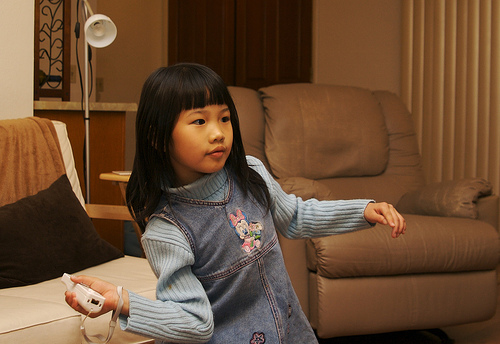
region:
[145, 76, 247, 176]
the head of a girl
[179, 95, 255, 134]
the eyes of a girl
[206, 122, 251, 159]
the nose of a girl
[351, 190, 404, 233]
the hand of a girl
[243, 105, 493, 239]
the arm of a girl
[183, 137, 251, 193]
the lips of a girl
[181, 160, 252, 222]
the chin of a girl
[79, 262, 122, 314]
the thumb of a girl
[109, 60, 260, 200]
the hair of a girl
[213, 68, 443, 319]
a couch in a house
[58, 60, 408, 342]
a little girl playing a video game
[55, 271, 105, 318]
a Wii remote in the girl's right hand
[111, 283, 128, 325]
a wrist strap on the girl's right wrist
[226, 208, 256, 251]
Minnie Mouse on the girl's denim dress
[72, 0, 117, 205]
a lamp in the family room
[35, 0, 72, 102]
a decorative wrought iron piece on the counter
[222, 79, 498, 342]
a beige leather recliner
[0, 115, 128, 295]
a blanket draped over the back of the sofa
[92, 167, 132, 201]
a wooden table behind the girl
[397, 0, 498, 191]
long blinds on the window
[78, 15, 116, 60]
lamp in the corner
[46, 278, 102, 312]
wii remote in hand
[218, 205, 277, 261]
minnie mouse on jumper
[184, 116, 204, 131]
eye of little girl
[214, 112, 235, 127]
eye of little girl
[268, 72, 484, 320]
recliner in the corner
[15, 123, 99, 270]
blanket in the corner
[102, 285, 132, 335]
bracelet on the remote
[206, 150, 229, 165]
mouth of the girl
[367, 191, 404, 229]
hand of the girl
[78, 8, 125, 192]
A white plastic and metal floor lamp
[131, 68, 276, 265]
A young girl with long black hair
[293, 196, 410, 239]
A left arm and hand in a blue long-sleeve garment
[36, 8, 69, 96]
A decorative built-in portion of a wall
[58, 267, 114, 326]
A white plastic game controller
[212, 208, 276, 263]
A Minnie Mouse embroidered patch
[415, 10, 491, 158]
A section of hanging draperies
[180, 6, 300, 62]
A pair of wooden cabinet doors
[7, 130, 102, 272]
A two-colored blanket draped over a chair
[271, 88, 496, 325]
A leather or vinyl reclining chair